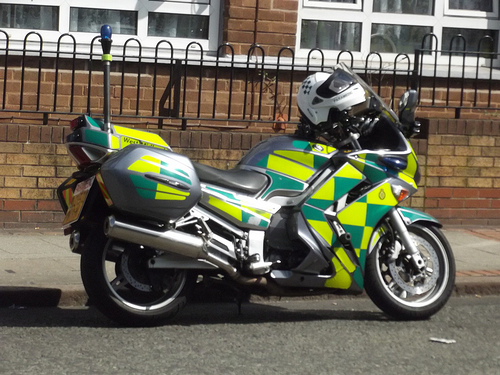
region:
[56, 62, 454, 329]
a green and yellow motorcycle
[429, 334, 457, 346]
a piece of trash on the road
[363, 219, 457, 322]
black and white motorcycle tire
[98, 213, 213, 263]
silver motorcycle exhaust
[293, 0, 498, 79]
white framed windows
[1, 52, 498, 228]
brick building behind motorcycle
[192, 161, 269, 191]
black motorcycle seat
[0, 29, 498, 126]
black metal rail behind motorcycle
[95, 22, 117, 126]
metal pole with blue light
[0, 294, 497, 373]
gray paved street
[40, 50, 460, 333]
green and yellow motorcycle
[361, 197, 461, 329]
small front wheel on motorcycle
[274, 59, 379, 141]
white helmet on front of motorcycle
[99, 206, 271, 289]
metal exhaust pipe on side of motorcycle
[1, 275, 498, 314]
cement curb of sidewalk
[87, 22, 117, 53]
blue bulb on top of metal pole on sidewalk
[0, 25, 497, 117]
metal fence on top of short brick wall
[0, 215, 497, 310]
cement sidewalk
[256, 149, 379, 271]
green and yellow asymetrical designs on side of motorcycle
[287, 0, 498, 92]
white framed window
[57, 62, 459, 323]
motorcycle is parked on the side of the street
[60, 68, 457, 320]
motorcycle is empty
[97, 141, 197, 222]
container is attached to motorcycle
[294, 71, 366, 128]
helmet rests on motorcycle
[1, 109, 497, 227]
wall is made of bricks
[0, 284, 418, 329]
shadow is cast by motorcycle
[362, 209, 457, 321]
wheel is attached to motorcycle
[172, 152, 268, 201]
seat is empty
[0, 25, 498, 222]
wall is next to sidewalk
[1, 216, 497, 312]
sidewalk is empty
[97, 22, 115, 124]
a blue light on a metal pole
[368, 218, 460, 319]
a rubber front tire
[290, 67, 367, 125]
a white motorcycle helmet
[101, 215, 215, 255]
a chrome motorcycle exhaust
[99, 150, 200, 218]
a container for storage on a motorcycle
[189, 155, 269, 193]
a black seat on a motorcycle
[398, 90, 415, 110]
a mirror on a motorcycle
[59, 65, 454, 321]
a green and yellow motorcycle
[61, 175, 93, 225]
a license plate on a motorcycle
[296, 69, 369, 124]
a white safety helmet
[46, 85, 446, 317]
bike on the street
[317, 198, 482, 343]
front tire of the bike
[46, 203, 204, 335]
back tire of the bike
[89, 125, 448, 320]
yellow and green bike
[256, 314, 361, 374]
street next to bike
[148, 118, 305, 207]
seat on the bike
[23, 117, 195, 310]
back of the bike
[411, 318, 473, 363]
item on the street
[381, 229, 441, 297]
Rim of a tire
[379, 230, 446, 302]
Rim of a tire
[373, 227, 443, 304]
Rim of a tire